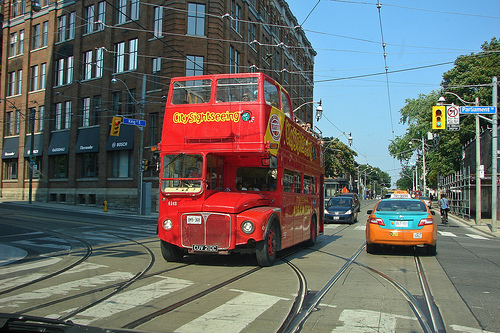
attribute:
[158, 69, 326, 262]
bus — red, double deck, tour bus, passenger bus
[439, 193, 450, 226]
person — riding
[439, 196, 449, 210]
shirt — blue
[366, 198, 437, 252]
taxi — orange, light blue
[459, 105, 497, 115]
street sign — blue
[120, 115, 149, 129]
street sign — blue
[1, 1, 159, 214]
building — tall, brown, large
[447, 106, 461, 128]
street sign — no turns, no left turn sign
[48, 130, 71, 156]
canopy — black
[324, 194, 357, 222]
car — black, behind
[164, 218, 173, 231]
headlight — is red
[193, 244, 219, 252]
license plate — black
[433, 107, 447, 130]
light — green, traffic light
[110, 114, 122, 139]
light — red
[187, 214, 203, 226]
license plate — white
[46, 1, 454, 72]
wires — utility wires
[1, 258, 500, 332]
crosswalk — painted